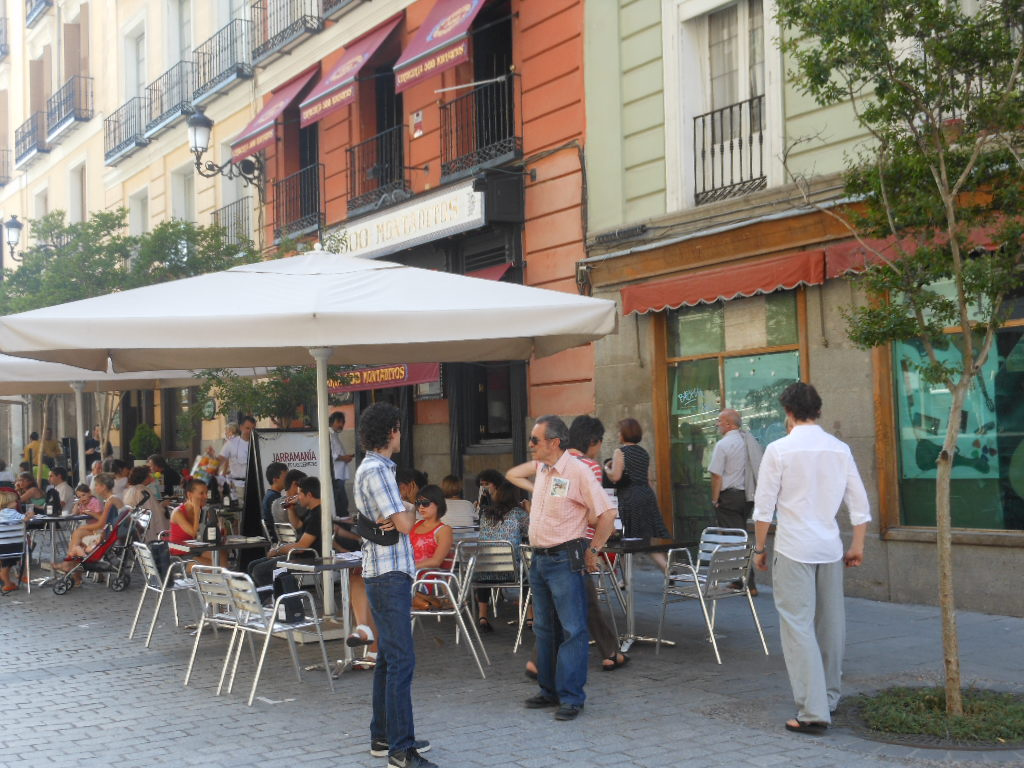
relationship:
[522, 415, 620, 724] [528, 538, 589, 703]
man wearing blue jeans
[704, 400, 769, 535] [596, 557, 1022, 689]
person walking on sidewalk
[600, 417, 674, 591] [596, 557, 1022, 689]
person walking on sidewalk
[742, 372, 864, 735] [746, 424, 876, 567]
man wearing a shirt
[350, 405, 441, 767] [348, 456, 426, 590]
man wearing a shirt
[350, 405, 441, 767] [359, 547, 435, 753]
man wearing blue jeans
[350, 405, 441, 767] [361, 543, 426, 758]
man wearing blue jeans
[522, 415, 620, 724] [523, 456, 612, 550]
man in a shirt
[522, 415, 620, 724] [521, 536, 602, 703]
man in blue jeans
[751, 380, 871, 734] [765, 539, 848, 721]
man in pants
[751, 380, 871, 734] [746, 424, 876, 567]
man in a shirt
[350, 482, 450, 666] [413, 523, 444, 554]
woman in a dress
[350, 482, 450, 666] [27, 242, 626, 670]
woman sitting under umbrella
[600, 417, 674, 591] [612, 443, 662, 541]
person in a dress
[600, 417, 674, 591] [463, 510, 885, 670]
person walking on street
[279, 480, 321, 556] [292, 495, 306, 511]
man drinking from a glass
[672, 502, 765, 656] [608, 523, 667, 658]
chair at table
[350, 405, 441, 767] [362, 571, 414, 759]
man wearing blue jeans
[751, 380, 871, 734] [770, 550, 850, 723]
man wearing pants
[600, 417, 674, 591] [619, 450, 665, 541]
person wearing a dress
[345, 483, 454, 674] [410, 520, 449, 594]
woman wearing dress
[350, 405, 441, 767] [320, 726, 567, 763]
man standing on sidewalk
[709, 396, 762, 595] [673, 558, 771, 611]
man standing on sidewalk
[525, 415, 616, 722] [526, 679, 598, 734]
man wearing shoes